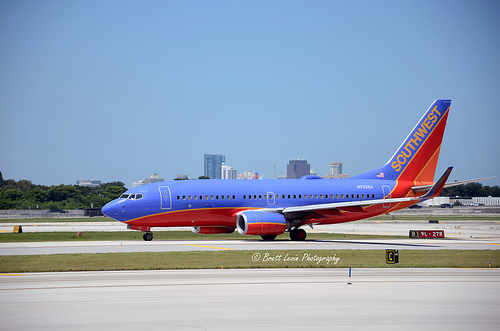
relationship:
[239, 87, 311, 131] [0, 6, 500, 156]
clouds in sky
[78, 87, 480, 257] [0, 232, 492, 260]
plane on runway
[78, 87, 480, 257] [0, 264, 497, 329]
plane on runway